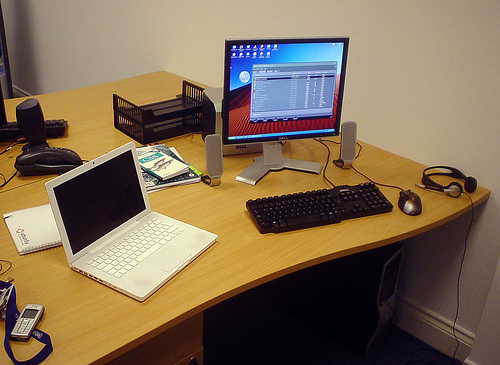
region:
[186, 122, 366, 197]
a set of computer speakers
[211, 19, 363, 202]
a computer monitor on a desk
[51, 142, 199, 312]
a white laptop on a desk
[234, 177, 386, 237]
a black computer keyboard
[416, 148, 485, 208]
a silver and black head set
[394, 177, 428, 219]
a silver and black computer mouse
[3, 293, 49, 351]
a silver cell phone on a desk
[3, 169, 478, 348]
a wood desk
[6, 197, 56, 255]
a spiral notebook on a desk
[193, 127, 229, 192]
a computer speaker on a desk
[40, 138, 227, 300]
White laptop on desk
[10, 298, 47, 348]
Silver phone on desk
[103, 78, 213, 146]
Black paper tray on desk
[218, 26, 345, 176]
Computer monitor on desk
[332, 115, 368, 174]
Gray speaker on desk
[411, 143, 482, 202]
Headphones laying on desk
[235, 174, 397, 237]
Black keyboard on desk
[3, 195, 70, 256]
white notebook laying on desk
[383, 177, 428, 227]
Black and silver mouse on desk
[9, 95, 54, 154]
Black speaker on desk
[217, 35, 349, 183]
A computer monitor with a gray base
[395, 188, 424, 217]
A black and silver computer mouse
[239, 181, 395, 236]
A black computer keyboard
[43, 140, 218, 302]
A white laptop computer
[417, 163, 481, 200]
Black and silver headphones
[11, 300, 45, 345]
A small silver cellular phone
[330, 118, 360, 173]
A small silver computer speaker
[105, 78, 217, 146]
Plastic trays on the desk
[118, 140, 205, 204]
A stack of books on the desk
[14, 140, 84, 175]
A black telephone on the desk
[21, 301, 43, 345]
A gray cellular phone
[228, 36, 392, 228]
A desktop computer on a desk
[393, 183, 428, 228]
A black and silver mouse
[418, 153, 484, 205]
A black and gray headset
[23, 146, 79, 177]
A black landline telephone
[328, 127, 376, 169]
A gray computer speaker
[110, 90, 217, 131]
A black memo holder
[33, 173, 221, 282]
A laptop sitting on a wooden desk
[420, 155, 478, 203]
Headphones lying on desk.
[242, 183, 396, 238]
Computer keyboard sitting on desk.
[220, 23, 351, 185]
Computer monitor sitting on desk.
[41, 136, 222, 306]
Laptop computer sitting on desk.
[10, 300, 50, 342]
Phone lying on desk.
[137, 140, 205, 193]
Books lying on desk.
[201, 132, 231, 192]
Computer speaker sitting on desk.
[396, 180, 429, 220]
Computer mouse sitting on desk.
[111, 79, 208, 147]
Desk organizer sitting on desk.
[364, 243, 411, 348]
Computer tower sitting on floor under desk.